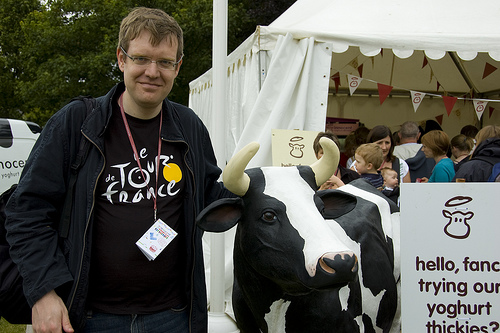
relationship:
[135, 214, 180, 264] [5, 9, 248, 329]
id on man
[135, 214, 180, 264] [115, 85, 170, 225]
id on lanyard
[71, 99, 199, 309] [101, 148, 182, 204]
shirt on logo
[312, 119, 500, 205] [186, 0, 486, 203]
people under tent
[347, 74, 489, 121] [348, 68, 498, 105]
banner on string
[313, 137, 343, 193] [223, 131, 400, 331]
horn on cow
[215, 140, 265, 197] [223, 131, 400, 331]
horn on cow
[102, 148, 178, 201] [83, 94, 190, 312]
logo on shirt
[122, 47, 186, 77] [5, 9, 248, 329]
glasses on man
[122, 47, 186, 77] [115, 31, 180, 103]
glasses on face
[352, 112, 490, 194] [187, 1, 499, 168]
people in tent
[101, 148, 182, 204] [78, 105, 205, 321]
logo on shirt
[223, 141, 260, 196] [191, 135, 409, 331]
horn on cow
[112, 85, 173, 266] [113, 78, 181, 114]
lanyard around neck